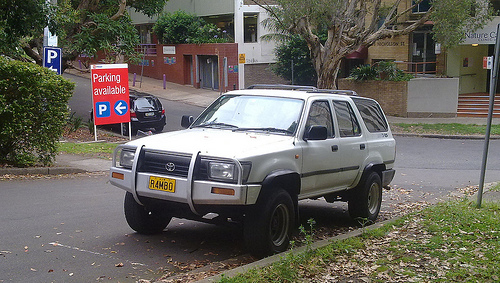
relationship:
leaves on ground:
[332, 204, 465, 273] [347, 196, 443, 270]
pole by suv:
[475, 72, 492, 224] [116, 75, 403, 202]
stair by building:
[471, 92, 499, 117] [370, 4, 489, 115]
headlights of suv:
[99, 131, 249, 190] [116, 75, 403, 202]